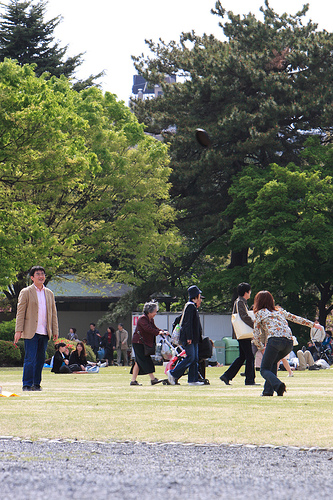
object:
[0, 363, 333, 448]
field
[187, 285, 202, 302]
hat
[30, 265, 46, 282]
hair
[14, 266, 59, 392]
man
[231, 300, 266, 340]
bag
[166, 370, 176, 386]
shoe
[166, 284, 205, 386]
man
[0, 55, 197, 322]
tree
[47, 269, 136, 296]
roof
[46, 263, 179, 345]
building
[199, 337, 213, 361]
purse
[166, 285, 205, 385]
woman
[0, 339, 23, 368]
rose bush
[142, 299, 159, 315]
hair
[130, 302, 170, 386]
woman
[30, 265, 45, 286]
head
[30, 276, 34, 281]
ear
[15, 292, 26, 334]
arm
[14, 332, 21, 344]
hand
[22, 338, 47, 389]
legs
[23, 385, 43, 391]
feet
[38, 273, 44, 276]
eyes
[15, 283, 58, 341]
jacket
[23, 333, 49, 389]
pants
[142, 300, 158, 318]
head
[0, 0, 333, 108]
sky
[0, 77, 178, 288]
leaves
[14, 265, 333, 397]
people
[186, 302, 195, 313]
shoulder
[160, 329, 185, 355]
stroller handle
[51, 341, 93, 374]
people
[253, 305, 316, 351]
shirt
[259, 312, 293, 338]
print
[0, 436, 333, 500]
dirt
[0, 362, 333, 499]
ground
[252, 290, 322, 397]
woman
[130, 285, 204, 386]
adults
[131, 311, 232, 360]
truck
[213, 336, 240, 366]
trashcans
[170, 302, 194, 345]
bag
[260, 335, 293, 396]
jeans